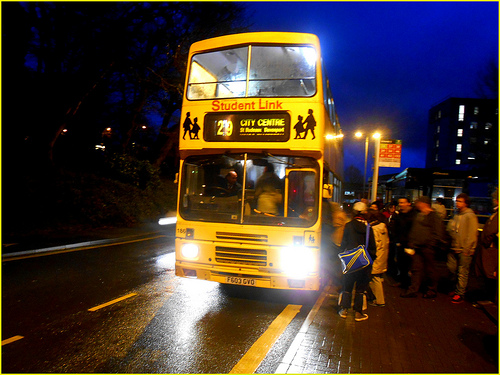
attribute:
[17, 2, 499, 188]
sky — dark blue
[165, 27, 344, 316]
bus — double-decker, tall, yellow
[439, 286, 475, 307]
shoe — red, black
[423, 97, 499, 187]
building — tall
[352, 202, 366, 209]
cap — white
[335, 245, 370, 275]
bag — blue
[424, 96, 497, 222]
building — tall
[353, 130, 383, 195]
lamp pole — tall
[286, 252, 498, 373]
sidewalk — brown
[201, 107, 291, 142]
sign — electric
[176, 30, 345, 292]
bus — double-decker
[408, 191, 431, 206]
hat — dark green